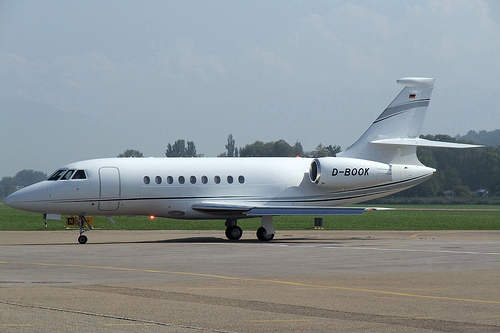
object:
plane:
[2, 77, 485, 246]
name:
[166, 209, 185, 217]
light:
[150, 215, 156, 219]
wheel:
[78, 234, 88, 245]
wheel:
[256, 226, 274, 241]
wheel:
[224, 227, 246, 239]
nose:
[5, 178, 47, 217]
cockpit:
[49, 160, 89, 187]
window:
[144, 176, 150, 184]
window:
[237, 175, 246, 184]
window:
[189, 175, 196, 184]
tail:
[337, 78, 484, 167]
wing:
[192, 201, 398, 212]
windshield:
[50, 168, 66, 182]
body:
[89, 157, 437, 219]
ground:
[1, 228, 497, 332]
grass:
[354, 206, 499, 231]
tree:
[166, 139, 197, 157]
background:
[2, 0, 500, 196]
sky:
[1, 0, 500, 179]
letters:
[329, 165, 373, 178]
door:
[98, 167, 123, 213]